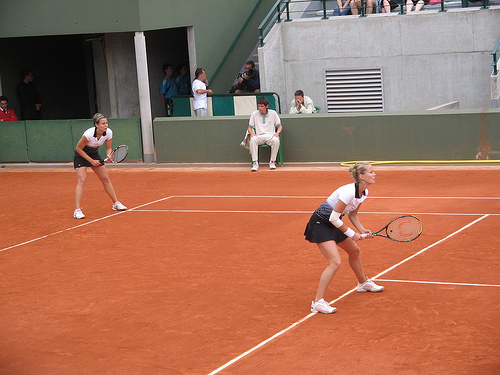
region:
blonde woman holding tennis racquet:
[300, 160, 421, 312]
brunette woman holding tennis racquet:
[71, 112, 128, 218]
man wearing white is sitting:
[241, 95, 284, 171]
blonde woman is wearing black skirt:
[302, 157, 384, 317]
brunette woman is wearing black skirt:
[73, 112, 126, 217]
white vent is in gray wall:
[321, 65, 385, 112]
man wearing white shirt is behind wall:
[187, 67, 212, 119]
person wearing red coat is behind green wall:
[0, 94, 17, 123]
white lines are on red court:
[202, 214, 489, 374]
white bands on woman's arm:
[326, 207, 356, 244]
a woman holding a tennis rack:
[63, 109, 135, 219]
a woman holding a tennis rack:
[294, 158, 429, 313]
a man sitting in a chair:
[241, 98, 296, 170]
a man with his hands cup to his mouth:
[286, 88, 316, 118]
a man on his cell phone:
[188, 67, 218, 117]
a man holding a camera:
[231, 55, 258, 94]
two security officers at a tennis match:
[159, 62, 189, 113]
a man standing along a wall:
[13, 69, 51, 121]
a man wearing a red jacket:
[0, 94, 21, 125]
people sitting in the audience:
[325, 0, 447, 17]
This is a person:
[290, 149, 398, 337]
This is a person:
[67, 102, 144, 230]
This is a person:
[238, 93, 289, 180]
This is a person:
[281, 81, 326, 148]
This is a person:
[234, 55, 266, 106]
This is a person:
[190, 56, 221, 127]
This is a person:
[152, 49, 190, 131]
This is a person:
[4, 76, 32, 177]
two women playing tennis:
[30, 108, 413, 331]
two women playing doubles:
[60, 110, 409, 342]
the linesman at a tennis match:
[237, 94, 289, 169]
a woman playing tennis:
[300, 155, 425, 320]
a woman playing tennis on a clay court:
[12, 105, 217, 355]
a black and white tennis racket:
[366, 212, 425, 246]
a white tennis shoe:
[305, 294, 342, 319]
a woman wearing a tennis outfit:
[306, 152, 381, 257]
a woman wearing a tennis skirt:
[303, 150, 381, 252]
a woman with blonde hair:
[346, 153, 383, 193]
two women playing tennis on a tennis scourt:
[75, 113, 423, 312]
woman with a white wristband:
[343, 228, 355, 239]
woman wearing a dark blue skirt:
[303, 216, 348, 244]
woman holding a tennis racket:
[353, 211, 423, 246]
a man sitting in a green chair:
[246, 95, 281, 171]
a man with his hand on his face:
[286, 89, 316, 112]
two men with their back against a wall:
[159, 61, 191, 114]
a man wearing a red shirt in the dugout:
[1, 94, 16, 122]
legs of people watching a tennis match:
[334, 0, 428, 15]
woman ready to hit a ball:
[74, 113, 129, 220]